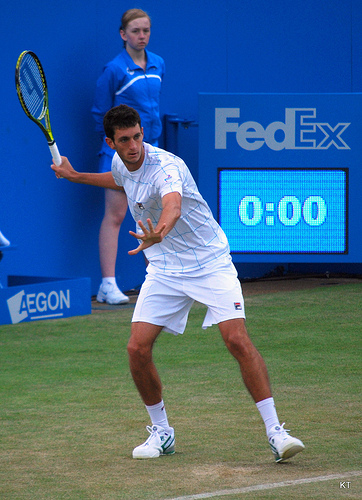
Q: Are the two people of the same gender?
A: No, they are both male and female.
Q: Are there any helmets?
A: No, there are no helmets.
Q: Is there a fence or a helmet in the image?
A: No, there are no helmets or fences.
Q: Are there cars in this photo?
A: No, there are no cars.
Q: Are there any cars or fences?
A: No, there are no cars or fences.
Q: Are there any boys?
A: No, there are no boys.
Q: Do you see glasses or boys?
A: No, there are no boys or glasses.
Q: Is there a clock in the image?
A: Yes, there is a clock.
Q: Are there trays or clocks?
A: Yes, there is a clock.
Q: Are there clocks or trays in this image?
A: Yes, there is a clock.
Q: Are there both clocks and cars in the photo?
A: No, there is a clock but no cars.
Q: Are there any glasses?
A: No, there are no glasses.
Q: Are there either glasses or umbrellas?
A: No, there are no glasses or umbrellas.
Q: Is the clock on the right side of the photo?
A: Yes, the clock is on the right of the image.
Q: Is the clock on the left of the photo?
A: No, the clock is on the right of the image.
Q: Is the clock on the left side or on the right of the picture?
A: The clock is on the right of the image.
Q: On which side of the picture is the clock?
A: The clock is on the right of the image.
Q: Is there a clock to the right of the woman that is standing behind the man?
A: Yes, there is a clock to the right of the woman.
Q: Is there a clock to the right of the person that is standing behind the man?
A: Yes, there is a clock to the right of the woman.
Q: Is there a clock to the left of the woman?
A: No, the clock is to the right of the woman.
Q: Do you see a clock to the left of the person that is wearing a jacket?
A: No, the clock is to the right of the woman.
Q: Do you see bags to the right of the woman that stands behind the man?
A: No, there is a clock to the right of the woman.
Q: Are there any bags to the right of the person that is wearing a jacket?
A: No, there is a clock to the right of the woman.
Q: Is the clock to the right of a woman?
A: Yes, the clock is to the right of a woman.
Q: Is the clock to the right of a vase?
A: No, the clock is to the right of a woman.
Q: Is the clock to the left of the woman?
A: No, the clock is to the right of the woman.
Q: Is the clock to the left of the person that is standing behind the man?
A: No, the clock is to the right of the woman.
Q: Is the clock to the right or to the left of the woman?
A: The clock is to the right of the woman.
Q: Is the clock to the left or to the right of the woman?
A: The clock is to the right of the woman.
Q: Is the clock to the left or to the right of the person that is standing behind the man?
A: The clock is to the right of the woman.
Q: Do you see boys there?
A: No, there are no boys.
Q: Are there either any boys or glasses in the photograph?
A: No, there are no boys or glasses.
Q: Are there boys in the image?
A: No, there are no boys.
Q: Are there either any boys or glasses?
A: No, there are no boys or glasses.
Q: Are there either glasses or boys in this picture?
A: No, there are no boys or glasses.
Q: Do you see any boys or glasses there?
A: No, there are no boys or glasses.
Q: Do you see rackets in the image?
A: Yes, there is a racket.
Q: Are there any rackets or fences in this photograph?
A: Yes, there is a racket.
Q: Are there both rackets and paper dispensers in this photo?
A: No, there is a racket but no paper dispensers.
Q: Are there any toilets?
A: No, there are no toilets.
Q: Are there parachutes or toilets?
A: No, there are no toilets or parachutes.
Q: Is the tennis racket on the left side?
A: Yes, the tennis racket is on the left of the image.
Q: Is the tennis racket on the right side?
A: No, the tennis racket is on the left of the image.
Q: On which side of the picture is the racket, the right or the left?
A: The racket is on the left of the image.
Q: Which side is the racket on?
A: The racket is on the left of the image.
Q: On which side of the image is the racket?
A: The racket is on the left of the image.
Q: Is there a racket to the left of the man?
A: Yes, there is a racket to the left of the man.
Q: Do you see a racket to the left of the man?
A: Yes, there is a racket to the left of the man.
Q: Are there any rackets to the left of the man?
A: Yes, there is a racket to the left of the man.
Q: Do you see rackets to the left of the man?
A: Yes, there is a racket to the left of the man.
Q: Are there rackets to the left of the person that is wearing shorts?
A: Yes, there is a racket to the left of the man.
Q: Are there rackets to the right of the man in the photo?
A: No, the racket is to the left of the man.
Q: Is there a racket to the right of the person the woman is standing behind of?
A: No, the racket is to the left of the man.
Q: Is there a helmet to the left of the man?
A: No, there is a racket to the left of the man.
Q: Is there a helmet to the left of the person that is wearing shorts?
A: No, there is a racket to the left of the man.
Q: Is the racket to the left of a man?
A: Yes, the racket is to the left of a man.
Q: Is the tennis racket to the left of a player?
A: No, the tennis racket is to the left of a man.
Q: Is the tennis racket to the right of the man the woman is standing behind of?
A: No, the tennis racket is to the left of the man.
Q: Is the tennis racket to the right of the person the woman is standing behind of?
A: No, the tennis racket is to the left of the man.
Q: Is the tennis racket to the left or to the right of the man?
A: The tennis racket is to the left of the man.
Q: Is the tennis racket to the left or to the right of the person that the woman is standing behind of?
A: The tennis racket is to the left of the man.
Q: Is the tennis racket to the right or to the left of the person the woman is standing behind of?
A: The tennis racket is to the left of the man.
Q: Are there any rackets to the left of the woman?
A: Yes, there is a racket to the left of the woman.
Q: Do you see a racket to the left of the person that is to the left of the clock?
A: Yes, there is a racket to the left of the woman.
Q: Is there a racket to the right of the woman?
A: No, the racket is to the left of the woman.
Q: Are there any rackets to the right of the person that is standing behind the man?
A: No, the racket is to the left of the woman.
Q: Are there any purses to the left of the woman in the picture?
A: No, there is a racket to the left of the woman.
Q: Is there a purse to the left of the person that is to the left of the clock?
A: No, there is a racket to the left of the woman.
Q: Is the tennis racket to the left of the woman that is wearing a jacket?
A: Yes, the tennis racket is to the left of the woman.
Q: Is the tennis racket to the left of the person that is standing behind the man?
A: Yes, the tennis racket is to the left of the woman.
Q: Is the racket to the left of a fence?
A: No, the racket is to the left of the woman.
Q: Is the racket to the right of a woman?
A: No, the racket is to the left of a woman.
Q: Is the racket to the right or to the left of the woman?
A: The racket is to the left of the woman.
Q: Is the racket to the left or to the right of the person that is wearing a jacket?
A: The racket is to the left of the woman.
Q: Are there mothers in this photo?
A: No, there are no mothers.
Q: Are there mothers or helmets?
A: No, there are no mothers or helmets.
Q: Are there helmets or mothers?
A: No, there are no mothers or helmets.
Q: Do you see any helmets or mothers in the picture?
A: No, there are no mothers or helmets.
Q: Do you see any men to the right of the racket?
A: Yes, there is a man to the right of the racket.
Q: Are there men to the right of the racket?
A: Yes, there is a man to the right of the racket.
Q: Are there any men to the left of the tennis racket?
A: No, the man is to the right of the tennis racket.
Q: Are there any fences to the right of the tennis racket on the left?
A: No, there is a man to the right of the racket.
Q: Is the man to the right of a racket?
A: Yes, the man is to the right of a racket.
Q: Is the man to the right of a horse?
A: No, the man is to the right of a racket.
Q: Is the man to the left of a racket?
A: No, the man is to the right of a racket.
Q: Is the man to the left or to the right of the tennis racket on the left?
A: The man is to the right of the tennis racket.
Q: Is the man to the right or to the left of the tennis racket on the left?
A: The man is to the right of the tennis racket.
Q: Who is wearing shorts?
A: The man is wearing shorts.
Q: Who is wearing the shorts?
A: The man is wearing shorts.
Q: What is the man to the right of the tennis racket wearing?
A: The man is wearing shorts.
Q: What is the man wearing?
A: The man is wearing shorts.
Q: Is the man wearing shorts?
A: Yes, the man is wearing shorts.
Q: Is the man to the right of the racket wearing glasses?
A: No, the man is wearing shorts.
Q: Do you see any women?
A: Yes, there is a woman.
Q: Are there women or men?
A: Yes, there is a woman.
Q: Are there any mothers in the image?
A: No, there are no mothers.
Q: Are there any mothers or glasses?
A: No, there are no mothers or glasses.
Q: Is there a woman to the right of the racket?
A: Yes, there is a woman to the right of the racket.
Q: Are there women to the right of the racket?
A: Yes, there is a woman to the right of the racket.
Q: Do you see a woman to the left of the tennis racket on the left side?
A: No, the woman is to the right of the racket.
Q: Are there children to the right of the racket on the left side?
A: No, there is a woman to the right of the tennis racket.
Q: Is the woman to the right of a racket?
A: Yes, the woman is to the right of a racket.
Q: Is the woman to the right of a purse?
A: No, the woman is to the right of a racket.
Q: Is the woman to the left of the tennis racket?
A: No, the woman is to the right of the tennis racket.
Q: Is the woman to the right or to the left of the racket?
A: The woman is to the right of the racket.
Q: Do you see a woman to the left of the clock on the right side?
A: Yes, there is a woman to the left of the clock.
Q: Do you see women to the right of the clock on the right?
A: No, the woman is to the left of the clock.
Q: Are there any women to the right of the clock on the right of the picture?
A: No, the woman is to the left of the clock.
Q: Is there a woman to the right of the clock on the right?
A: No, the woman is to the left of the clock.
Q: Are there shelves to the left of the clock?
A: No, there is a woman to the left of the clock.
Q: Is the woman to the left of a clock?
A: Yes, the woman is to the left of a clock.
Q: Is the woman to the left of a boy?
A: No, the woman is to the left of a clock.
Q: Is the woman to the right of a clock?
A: No, the woman is to the left of a clock.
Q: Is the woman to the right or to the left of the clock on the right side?
A: The woman is to the left of the clock.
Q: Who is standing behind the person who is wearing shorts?
A: The woman is standing behind the man.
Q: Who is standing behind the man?
A: The woman is standing behind the man.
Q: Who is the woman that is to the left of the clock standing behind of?
A: The woman is standing behind the man.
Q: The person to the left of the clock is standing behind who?
A: The woman is standing behind the man.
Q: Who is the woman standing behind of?
A: The woman is standing behind the man.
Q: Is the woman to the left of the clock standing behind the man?
A: Yes, the woman is standing behind the man.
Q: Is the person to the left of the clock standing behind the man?
A: Yes, the woman is standing behind the man.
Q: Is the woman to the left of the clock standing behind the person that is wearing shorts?
A: Yes, the woman is standing behind the man.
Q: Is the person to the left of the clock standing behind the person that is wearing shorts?
A: Yes, the woman is standing behind the man.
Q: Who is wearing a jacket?
A: The woman is wearing a jacket.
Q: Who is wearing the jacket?
A: The woman is wearing a jacket.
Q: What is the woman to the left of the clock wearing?
A: The woman is wearing a jacket.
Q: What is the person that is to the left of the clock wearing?
A: The woman is wearing a jacket.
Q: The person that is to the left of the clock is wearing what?
A: The woman is wearing a jacket.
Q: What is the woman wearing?
A: The woman is wearing a jacket.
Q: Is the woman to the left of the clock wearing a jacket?
A: Yes, the woman is wearing a jacket.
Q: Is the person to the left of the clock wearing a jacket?
A: Yes, the woman is wearing a jacket.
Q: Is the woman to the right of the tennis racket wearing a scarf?
A: No, the woman is wearing a jacket.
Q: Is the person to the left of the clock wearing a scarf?
A: No, the woman is wearing a jacket.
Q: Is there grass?
A: Yes, there is grass.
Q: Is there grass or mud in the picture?
A: Yes, there is grass.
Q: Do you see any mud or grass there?
A: Yes, there is grass.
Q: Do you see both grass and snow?
A: No, there is grass but no snow.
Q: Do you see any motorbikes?
A: No, there are no motorbikes.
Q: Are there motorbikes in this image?
A: No, there are no motorbikes.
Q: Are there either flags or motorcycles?
A: No, there are no motorcycles or flags.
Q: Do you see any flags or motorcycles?
A: No, there are no motorcycles or flags.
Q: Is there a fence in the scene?
A: No, there are no fences.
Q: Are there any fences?
A: No, there are no fences.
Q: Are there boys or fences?
A: No, there are no fences or boys.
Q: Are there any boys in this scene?
A: No, there are no boys.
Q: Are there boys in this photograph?
A: No, there are no boys.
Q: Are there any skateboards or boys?
A: No, there are no boys or skateboards.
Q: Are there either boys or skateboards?
A: No, there are no boys or skateboards.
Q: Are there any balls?
A: No, there are no balls.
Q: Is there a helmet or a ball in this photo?
A: No, there are no balls or helmets.